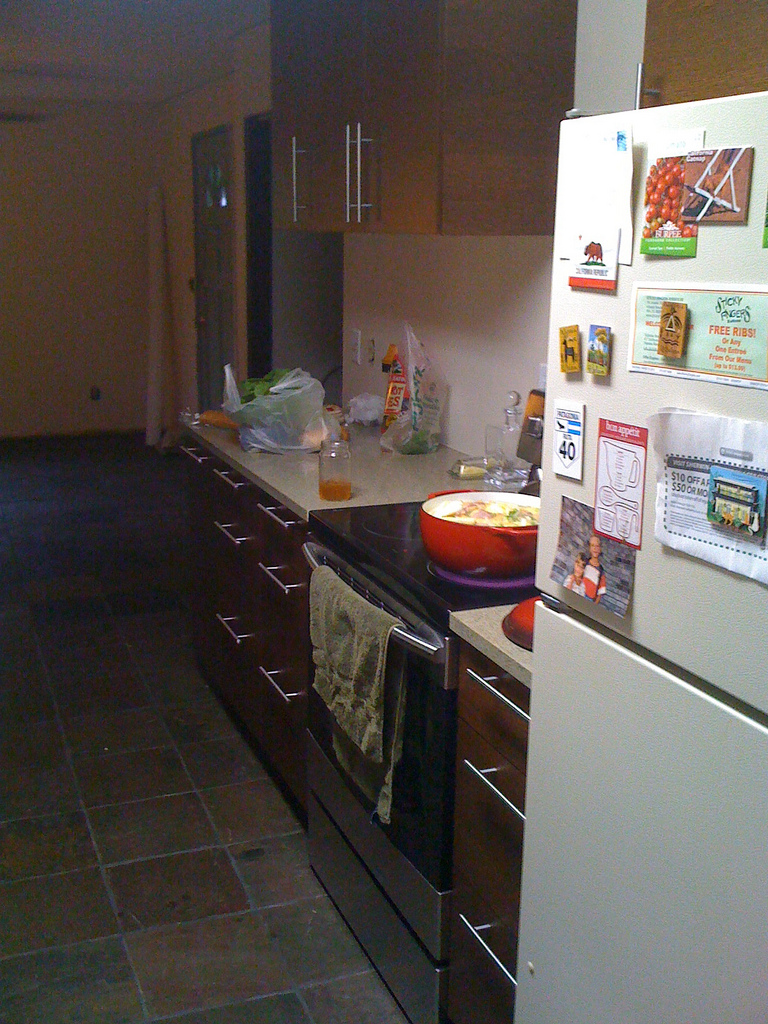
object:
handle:
[206, 507, 254, 553]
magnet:
[584, 413, 654, 552]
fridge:
[507, 85, 765, 1018]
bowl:
[414, 465, 543, 586]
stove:
[276, 490, 447, 1019]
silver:
[412, 632, 437, 651]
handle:
[260, 663, 304, 706]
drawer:
[443, 726, 526, 939]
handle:
[456, 756, 521, 826]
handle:
[456, 911, 517, 985]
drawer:
[443, 877, 517, 1022]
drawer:
[254, 551, 308, 638]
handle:
[258, 555, 304, 594]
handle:
[213, 608, 248, 649]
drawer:
[445, 863, 519, 1022]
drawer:
[447, 710, 529, 923]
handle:
[460, 671, 529, 714]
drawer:
[450, 635, 537, 750]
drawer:
[253, 643, 303, 793]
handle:
[259, 663, 299, 706]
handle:
[215, 603, 252, 650]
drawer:
[211, 584, 252, 726]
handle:
[249, 553, 313, 614]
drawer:
[239, 526, 321, 660]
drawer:
[243, 484, 317, 571]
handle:
[247, 495, 303, 541]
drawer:
[194, 495, 268, 580]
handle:
[203, 498, 260, 567]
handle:
[198, 451, 254, 511]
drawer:
[197, 452, 258, 521]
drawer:
[173, 424, 219, 489]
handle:
[173, 438, 212, 474]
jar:
[311, 435, 357, 506]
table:
[170, 384, 526, 523]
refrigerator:
[510, 69, 765, 1017]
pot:
[409, 490, 557, 573]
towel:
[303, 553, 406, 833]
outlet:
[349, 321, 371, 376]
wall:
[336, 5, 539, 450]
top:
[496, 591, 552, 651]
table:
[445, 595, 531, 682]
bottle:
[482, 388, 534, 497]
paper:
[588, 413, 655, 555]